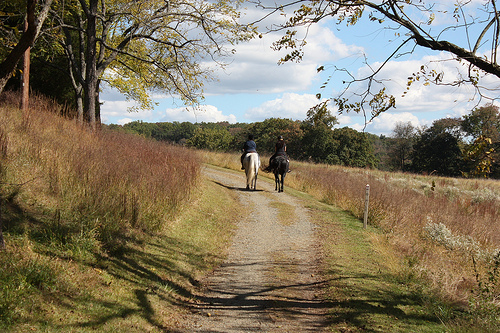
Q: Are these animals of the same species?
A: Yes, all the animals are horses.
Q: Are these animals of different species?
A: No, all the animals are horses.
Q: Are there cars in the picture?
A: No, there are no cars.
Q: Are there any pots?
A: No, there are no pots.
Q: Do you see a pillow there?
A: No, there are no pillows.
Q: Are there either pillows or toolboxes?
A: No, there are no pillows or toolboxes.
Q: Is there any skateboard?
A: No, there are no skateboards.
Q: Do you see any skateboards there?
A: No, there are no skateboards.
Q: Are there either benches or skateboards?
A: No, there are no skateboards or benches.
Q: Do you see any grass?
A: Yes, there is grass.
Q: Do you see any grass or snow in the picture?
A: Yes, there is grass.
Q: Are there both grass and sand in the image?
A: No, there is grass but no sand.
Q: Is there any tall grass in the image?
A: Yes, there is tall grass.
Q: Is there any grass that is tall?
A: Yes, there is grass that is tall.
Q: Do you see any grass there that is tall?
A: Yes, there is grass that is tall.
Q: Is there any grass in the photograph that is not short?
A: Yes, there is tall grass.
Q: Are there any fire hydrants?
A: No, there are no fire hydrants.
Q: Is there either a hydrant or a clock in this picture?
A: No, there are no fire hydrants or clocks.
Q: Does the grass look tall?
A: Yes, the grass is tall.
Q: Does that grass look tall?
A: Yes, the grass is tall.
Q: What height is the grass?
A: The grass is tall.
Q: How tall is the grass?
A: The grass is tall.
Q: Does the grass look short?
A: No, the grass is tall.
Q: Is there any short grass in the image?
A: No, there is grass but it is tall.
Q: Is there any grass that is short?
A: No, there is grass but it is tall.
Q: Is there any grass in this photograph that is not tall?
A: No, there is grass but it is tall.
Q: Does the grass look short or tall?
A: The grass is tall.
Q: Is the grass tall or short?
A: The grass is tall.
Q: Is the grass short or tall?
A: The grass is tall.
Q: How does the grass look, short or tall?
A: The grass is tall.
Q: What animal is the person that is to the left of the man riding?
A: The person is riding a horse.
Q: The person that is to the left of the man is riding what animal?
A: The person is riding a horse.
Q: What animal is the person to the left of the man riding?
A: The person is riding a horse.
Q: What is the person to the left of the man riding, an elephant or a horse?
A: The person is riding a horse.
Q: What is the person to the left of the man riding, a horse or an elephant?
A: The person is riding a horse.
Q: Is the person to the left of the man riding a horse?
A: Yes, the person is riding a horse.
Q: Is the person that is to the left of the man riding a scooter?
A: No, the person is riding a horse.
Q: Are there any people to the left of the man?
A: Yes, there is a person to the left of the man.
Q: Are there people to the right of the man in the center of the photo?
A: No, the person is to the left of the man.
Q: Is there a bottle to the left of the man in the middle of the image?
A: No, there is a person to the left of the man.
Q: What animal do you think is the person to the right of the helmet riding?
A: The person is riding a horse.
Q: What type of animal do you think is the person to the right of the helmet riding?
A: The person is riding a horse.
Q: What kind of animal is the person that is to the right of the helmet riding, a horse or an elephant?
A: The person is riding a horse.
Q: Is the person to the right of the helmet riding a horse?
A: Yes, the person is riding a horse.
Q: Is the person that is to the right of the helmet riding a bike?
A: No, the person is riding a horse.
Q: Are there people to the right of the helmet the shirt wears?
A: Yes, there is a person to the right of the helmet.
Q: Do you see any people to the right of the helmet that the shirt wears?
A: Yes, there is a person to the right of the helmet.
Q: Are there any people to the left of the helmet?
A: No, the person is to the right of the helmet.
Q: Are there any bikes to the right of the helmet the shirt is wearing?
A: No, there is a person to the right of the helmet.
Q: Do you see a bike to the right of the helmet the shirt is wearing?
A: No, there is a person to the right of the helmet.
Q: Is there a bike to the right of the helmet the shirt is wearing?
A: No, there is a person to the right of the helmet.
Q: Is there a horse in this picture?
A: Yes, there is a horse.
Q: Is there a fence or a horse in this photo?
A: Yes, there is a horse.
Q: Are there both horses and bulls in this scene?
A: No, there is a horse but no bulls.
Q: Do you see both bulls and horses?
A: No, there is a horse but no bulls.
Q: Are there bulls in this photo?
A: No, there are no bulls.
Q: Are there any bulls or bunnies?
A: No, there are no bulls or bunnies.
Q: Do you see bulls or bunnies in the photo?
A: No, there are no bulls or bunnies.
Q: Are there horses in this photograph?
A: Yes, there is a horse.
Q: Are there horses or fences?
A: Yes, there is a horse.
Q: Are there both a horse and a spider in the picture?
A: No, there is a horse but no spiders.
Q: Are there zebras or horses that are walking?
A: Yes, the horse is walking.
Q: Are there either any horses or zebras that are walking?
A: Yes, the horse is walking.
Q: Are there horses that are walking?
A: Yes, there is a horse that is walking.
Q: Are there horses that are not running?
A: Yes, there is a horse that is walking.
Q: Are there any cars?
A: No, there are no cars.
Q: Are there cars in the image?
A: No, there are no cars.